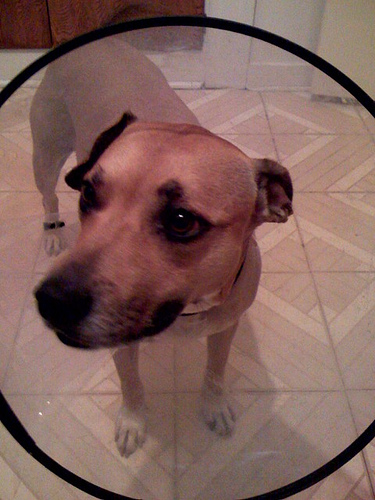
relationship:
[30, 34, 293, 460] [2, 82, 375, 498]
dog on floor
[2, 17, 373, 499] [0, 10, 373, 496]
cone with edge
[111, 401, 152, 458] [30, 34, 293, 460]
paw on dog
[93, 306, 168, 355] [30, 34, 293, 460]
whiskers on dog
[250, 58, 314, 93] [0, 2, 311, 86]
baseboard on wall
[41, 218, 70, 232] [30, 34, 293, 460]
bracelet on dog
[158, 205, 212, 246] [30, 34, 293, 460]
eye of dog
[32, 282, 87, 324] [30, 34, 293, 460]
nose on dog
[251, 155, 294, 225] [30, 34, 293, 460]
ear on dog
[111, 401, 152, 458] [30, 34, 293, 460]
paw of dog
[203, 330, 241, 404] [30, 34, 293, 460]
leg of dog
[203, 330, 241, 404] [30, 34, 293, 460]
leg with dog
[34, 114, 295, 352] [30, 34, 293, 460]
head of dog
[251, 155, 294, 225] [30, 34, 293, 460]
ear of dog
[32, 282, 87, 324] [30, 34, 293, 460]
nose of dog